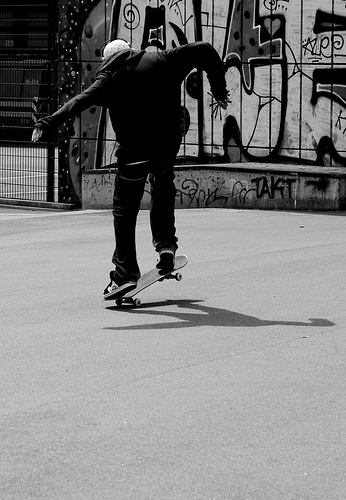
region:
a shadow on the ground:
[156, 301, 320, 338]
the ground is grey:
[176, 393, 302, 479]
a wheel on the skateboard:
[175, 272, 187, 282]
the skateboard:
[142, 270, 156, 282]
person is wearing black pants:
[113, 202, 137, 273]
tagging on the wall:
[234, 13, 338, 125]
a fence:
[2, 16, 57, 104]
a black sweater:
[118, 71, 171, 136]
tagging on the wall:
[185, 178, 227, 207]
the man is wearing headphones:
[64, 30, 214, 100]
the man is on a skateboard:
[89, 259, 334, 310]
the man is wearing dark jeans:
[65, 191, 282, 253]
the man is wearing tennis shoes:
[77, 247, 250, 339]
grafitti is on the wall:
[187, 48, 305, 166]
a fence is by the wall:
[10, 40, 116, 231]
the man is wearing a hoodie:
[61, 50, 322, 189]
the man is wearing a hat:
[84, 18, 163, 103]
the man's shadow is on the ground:
[92, 261, 338, 385]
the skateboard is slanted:
[93, 236, 314, 322]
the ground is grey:
[153, 406, 241, 462]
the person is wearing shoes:
[93, 278, 124, 289]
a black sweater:
[106, 76, 169, 137]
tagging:
[250, 173, 290, 199]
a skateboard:
[140, 270, 155, 278]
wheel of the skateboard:
[173, 269, 183, 279]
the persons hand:
[25, 125, 42, 140]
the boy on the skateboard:
[31, 37, 229, 299]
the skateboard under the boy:
[103, 253, 187, 305]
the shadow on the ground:
[102, 298, 334, 329]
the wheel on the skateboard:
[174, 271, 181, 280]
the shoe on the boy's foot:
[102, 270, 136, 300]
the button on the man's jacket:
[155, 248, 174, 270]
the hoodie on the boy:
[33, 41, 228, 164]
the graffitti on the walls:
[57, 0, 345, 210]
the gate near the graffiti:
[0, 0, 57, 202]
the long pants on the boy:
[112, 146, 178, 281]